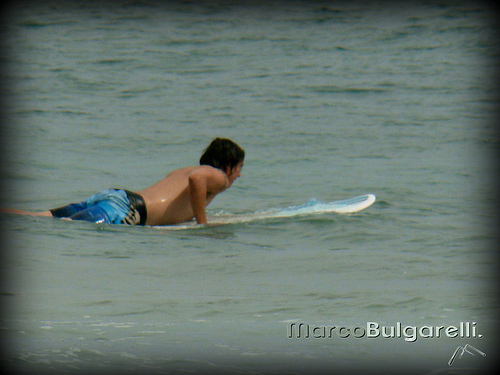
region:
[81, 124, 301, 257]
man on surf board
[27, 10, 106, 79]
white clouds in blue sky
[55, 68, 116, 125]
white clouds in blue sky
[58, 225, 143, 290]
white clouds in blue sky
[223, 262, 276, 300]
white clouds in blue sky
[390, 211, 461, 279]
white clouds in blue sky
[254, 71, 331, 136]
white clouds in blue sky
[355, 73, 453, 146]
white clouds in blue sky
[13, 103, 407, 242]
man laying on a surfboard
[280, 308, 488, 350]
the photographers watermark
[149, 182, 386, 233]
long white surfboard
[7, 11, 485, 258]
photograph taken at the ocean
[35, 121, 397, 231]
man on surfboard paddeling out to sea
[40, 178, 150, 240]
man wearing swim trunks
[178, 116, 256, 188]
man with dark wet hair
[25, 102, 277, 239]
man wearing no shirt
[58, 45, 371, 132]
calm blue ocean water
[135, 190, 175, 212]
light reflecting off of man's back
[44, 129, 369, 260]
young man on surf board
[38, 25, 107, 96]
white and blue ocean waves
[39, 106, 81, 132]
white and blue ocean waves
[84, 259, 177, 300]
white and blue ocean waves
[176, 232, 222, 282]
white and blue ocean waves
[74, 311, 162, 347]
white and blue ocean waves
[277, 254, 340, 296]
white and blue ocean waves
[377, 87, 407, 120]
white and blue ocean waves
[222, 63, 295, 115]
white and blue ocean waves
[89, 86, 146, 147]
white and blue ocean waves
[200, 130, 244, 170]
The man's hair is black.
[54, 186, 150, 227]
The man's shorts are blue and black.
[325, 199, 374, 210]
The surfboard is blue and white.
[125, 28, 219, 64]
The water is dark blue.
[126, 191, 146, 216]
The waist on the man's shorts is black.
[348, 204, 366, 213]
The trim of the surfboard is white.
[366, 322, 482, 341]
The writing is in white.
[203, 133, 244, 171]
Hair is on the man's cheek.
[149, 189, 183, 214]
The man's back is showing.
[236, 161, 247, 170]
The man's eyebrow is black.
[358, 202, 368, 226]
part of the ocea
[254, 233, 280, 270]
part of the sea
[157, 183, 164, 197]
back of a man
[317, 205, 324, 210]
part of a board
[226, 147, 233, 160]
head of a man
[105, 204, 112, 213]
part of a short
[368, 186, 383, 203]
tip of a board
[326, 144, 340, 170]
part of the sea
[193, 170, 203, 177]
part of an elbow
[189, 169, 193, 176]
edge of an elbow